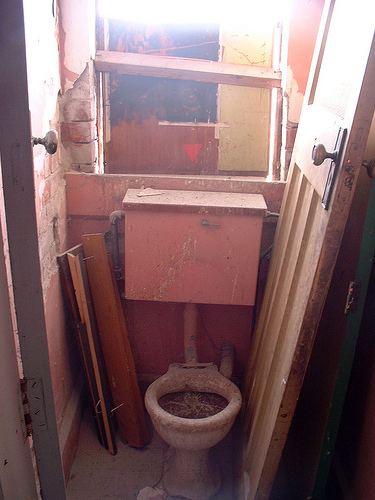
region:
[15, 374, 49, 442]
rusted hinge on bathroom door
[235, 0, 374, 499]
door leaning against a wall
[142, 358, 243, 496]
filthy rusted out toilet bowl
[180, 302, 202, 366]
paint chipping off of toilet pipe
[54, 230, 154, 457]
stack of boards with bent nails in them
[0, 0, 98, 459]
brick wall with paper peeling off of it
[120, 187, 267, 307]
old square toilet tank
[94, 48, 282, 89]
broken wood construction framing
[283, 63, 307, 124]
paint peeling off of a wall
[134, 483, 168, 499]
wadded up paper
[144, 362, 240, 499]
old dusty white toilet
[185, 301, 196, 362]
pink tube behind the toilet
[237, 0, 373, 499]
wooden door by the toilet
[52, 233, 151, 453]
pieces of wood by the toilet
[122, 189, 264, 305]
water tank above the toilet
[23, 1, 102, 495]
brick wall by the toilet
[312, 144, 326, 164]
metal door handle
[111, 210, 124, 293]
metal pipe by the tank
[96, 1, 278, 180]
window behind the toilet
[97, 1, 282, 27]
light reflection above the toilet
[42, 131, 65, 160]
door knob on the door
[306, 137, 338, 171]
bronze door knob on door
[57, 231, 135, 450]
wood planks in bathroom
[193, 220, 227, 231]
toilet handle to flush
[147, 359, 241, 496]
rusted white toilet on floor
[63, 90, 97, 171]
brick wall in the room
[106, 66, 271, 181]
window in the room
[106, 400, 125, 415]
nail in the wood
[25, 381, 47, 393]
white screw in the door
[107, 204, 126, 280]
a pipe attached to toilet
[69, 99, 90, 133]
Paint peeling off the wall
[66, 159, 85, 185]
Paint peeling off the wall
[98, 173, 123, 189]
Paint peeling off the wall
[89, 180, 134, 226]
Paint peeling off the wall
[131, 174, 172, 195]
Paint peeling off the wall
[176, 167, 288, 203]
Paint peeling off the wall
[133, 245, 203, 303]
Paint peeling off the wall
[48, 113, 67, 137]
Paint peeling off the wall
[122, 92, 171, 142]
Paint peeling off the wall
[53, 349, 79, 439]
Paint peeling off the wall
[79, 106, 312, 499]
an old and dirty toilet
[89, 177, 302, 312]
the tank is pink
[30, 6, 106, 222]
exposed brick in the wall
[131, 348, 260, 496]
the toilet bowl is empty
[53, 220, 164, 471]
wood panels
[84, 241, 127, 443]
there are exposed nails in the wood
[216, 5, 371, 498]
this door is not mounted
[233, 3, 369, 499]
the door is off its hinges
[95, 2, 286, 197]
the window is boarded up and painted over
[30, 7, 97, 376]
the paint on the wall is peeling